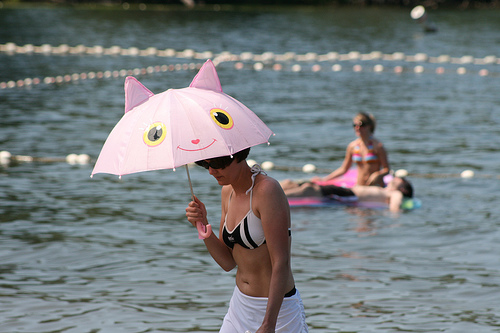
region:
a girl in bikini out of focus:
[346, 114, 388, 184]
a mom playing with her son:
[289, 113, 411, 212]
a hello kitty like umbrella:
[106, 66, 265, 166]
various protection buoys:
[251, 44, 498, 81]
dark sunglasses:
[196, 156, 235, 172]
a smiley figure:
[138, 108, 236, 154]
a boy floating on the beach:
[293, 177, 420, 204]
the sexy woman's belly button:
[239, 277, 251, 287]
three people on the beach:
[183, 81, 424, 331]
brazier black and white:
[219, 201, 264, 249]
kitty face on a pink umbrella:
[64, 59, 282, 184]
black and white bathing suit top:
[207, 185, 299, 254]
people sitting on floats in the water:
[293, 102, 415, 229]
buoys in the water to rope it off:
[247, 33, 461, 93]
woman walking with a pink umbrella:
[85, 56, 342, 330]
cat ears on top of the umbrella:
[103, 53, 225, 108]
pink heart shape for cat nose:
[180, 130, 207, 145]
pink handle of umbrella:
[191, 217, 216, 243]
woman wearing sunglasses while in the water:
[344, 111, 386, 180]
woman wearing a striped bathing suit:
[344, 113, 385, 168]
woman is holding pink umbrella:
[95, 89, 268, 206]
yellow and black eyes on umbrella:
[145, 106, 249, 143]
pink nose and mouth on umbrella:
[165, 128, 230, 161]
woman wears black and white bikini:
[212, 187, 264, 262]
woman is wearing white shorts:
[196, 285, 283, 332]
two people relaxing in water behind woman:
[285, 103, 406, 225]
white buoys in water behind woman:
[0, 8, 427, 208]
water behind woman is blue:
[16, 190, 126, 325]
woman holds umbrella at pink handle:
[160, 213, 222, 270]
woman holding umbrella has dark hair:
[195, 144, 250, 174]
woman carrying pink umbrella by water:
[50, 26, 465, 311]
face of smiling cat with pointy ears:
[110, 60, 270, 160]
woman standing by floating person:
[292, 106, 417, 211]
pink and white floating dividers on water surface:
[12, 31, 478, 183]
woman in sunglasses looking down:
[192, 151, 247, 183]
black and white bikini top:
[210, 175, 290, 247]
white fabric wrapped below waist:
[211, 280, 311, 325]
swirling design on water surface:
[35, 202, 180, 322]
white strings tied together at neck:
[240, 152, 267, 203]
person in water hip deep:
[315, 107, 392, 188]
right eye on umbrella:
[206, 99, 243, 137]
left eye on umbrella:
[146, 101, 175, 156]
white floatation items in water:
[375, 33, 492, 88]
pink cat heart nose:
[188, 136, 203, 148]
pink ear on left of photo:
[116, 73, 160, 108]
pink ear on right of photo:
[191, 57, 223, 97]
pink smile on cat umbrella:
[166, 140, 230, 155]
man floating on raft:
[305, 175, 437, 211]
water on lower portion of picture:
[345, 249, 497, 324]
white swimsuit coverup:
[232, 285, 326, 330]